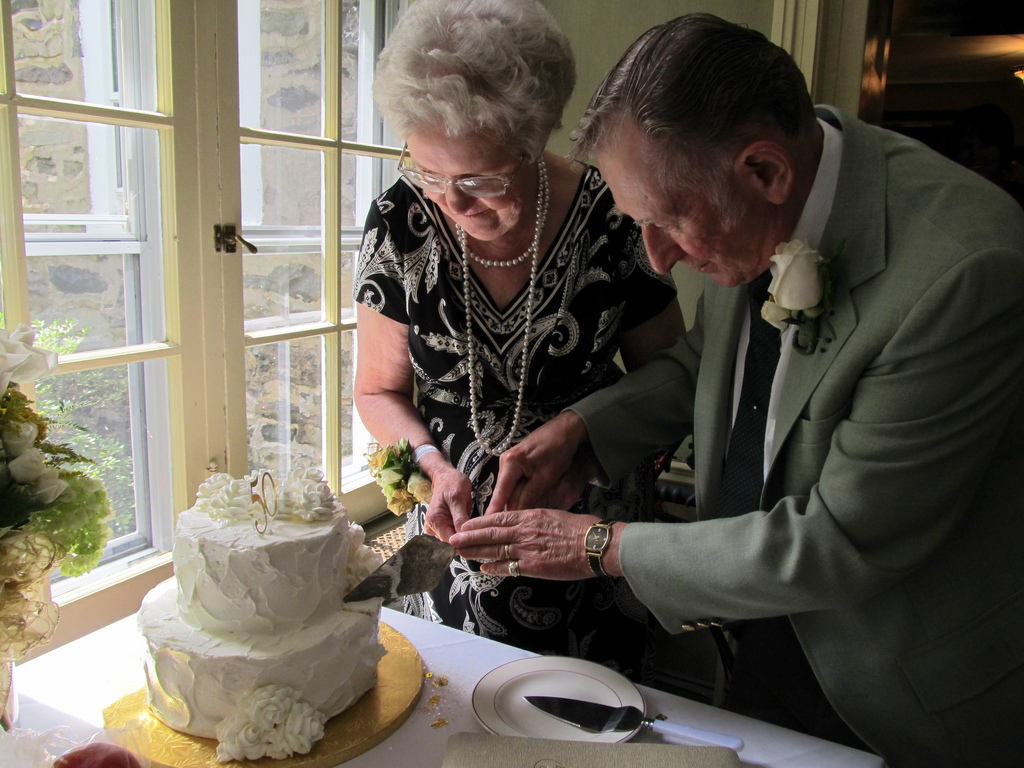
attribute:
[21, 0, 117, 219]
glass — clean, clear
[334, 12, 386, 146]
glass — clean, clear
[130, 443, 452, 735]
cake — two layer, small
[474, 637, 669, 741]
plate — small, white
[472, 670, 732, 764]
cake spatula — white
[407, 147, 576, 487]
pearls — long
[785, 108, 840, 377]
shirt collar — white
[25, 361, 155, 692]
flowers — green, white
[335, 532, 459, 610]
utensil — silver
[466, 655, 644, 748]
plate — white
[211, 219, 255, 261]
window latch — dark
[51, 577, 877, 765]
tablecloth — white